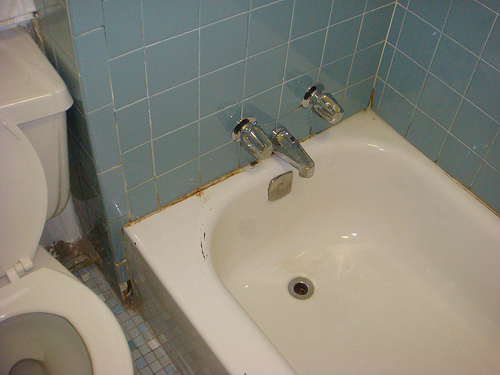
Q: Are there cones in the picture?
A: No, there are no cones.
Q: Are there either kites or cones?
A: No, there are no cones or kites.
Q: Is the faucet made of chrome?
A: Yes, the faucet is made of chrome.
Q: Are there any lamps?
A: No, there are no lamps.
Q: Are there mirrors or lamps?
A: No, there are no lamps or mirrors.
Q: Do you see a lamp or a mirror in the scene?
A: No, there are no lamps or mirrors.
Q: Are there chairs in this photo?
A: No, there are no chairs.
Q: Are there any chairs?
A: No, there are no chairs.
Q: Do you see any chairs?
A: No, there are no chairs.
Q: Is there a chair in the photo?
A: No, there are no chairs.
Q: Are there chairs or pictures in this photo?
A: No, there are no chairs or pictures.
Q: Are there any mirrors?
A: No, there are no mirrors.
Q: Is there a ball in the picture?
A: No, there are no balls.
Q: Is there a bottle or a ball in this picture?
A: No, there are no balls or bottles.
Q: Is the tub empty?
A: Yes, the tub is empty.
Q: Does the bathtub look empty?
A: Yes, the bathtub is empty.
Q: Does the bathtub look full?
A: No, the bathtub is empty.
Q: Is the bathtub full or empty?
A: The bathtub is empty.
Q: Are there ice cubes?
A: No, there are no ice cubes.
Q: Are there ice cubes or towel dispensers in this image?
A: No, there are no ice cubes or towel dispensers.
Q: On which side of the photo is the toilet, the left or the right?
A: The toilet is on the left of the image.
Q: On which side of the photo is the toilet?
A: The toilet is on the left of the image.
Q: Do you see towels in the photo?
A: Yes, there is a towel.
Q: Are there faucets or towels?
A: Yes, there is a towel.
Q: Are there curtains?
A: No, there are no curtains.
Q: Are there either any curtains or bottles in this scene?
A: No, there are no curtains or bottles.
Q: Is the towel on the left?
A: Yes, the towel is on the left of the image.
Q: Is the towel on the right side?
A: No, the towel is on the left of the image.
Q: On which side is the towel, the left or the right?
A: The towel is on the left of the image.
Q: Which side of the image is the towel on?
A: The towel is on the left of the image.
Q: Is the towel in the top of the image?
A: Yes, the towel is in the top of the image.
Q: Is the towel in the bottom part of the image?
A: No, the towel is in the top of the image.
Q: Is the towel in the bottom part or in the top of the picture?
A: The towel is in the top of the image.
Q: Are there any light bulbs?
A: No, there are no light bulbs.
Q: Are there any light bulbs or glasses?
A: No, there are no light bulbs or glasses.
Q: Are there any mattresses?
A: No, there are no mattresses.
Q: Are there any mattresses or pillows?
A: No, there are no mattresses or pillows.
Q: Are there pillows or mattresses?
A: No, there are no mattresses or pillows.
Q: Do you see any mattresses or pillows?
A: No, there are no mattresses or pillows.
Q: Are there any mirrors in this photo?
A: No, there are no mirrors.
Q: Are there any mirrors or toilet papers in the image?
A: No, there are no mirrors or toilet papers.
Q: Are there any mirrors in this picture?
A: No, there are no mirrors.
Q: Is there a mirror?
A: No, there are no mirrors.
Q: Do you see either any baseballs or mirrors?
A: No, there are no mirrors or baseballs.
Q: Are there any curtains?
A: No, there are no curtains.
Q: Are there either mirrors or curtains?
A: No, there are no curtains or mirrors.